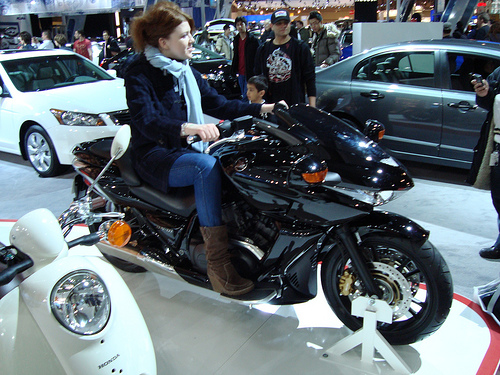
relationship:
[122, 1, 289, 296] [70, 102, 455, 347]
woman on bike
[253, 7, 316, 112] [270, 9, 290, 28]
man wearing hat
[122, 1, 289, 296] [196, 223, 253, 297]
woman wearing boot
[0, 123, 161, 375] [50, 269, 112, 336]
scooter has headlight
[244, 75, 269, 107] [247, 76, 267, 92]
boy has hair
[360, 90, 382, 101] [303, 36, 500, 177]
handle on car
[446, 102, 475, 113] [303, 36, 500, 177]
handle on car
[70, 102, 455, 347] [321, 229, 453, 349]
bike has wheel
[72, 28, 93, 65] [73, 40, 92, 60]
man wearing shirt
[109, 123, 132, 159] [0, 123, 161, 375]
mirror on scooter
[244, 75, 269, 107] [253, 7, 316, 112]
boy in front of man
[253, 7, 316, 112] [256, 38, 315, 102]
man wearing shirt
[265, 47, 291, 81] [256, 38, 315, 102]
design on shirt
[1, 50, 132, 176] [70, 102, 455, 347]
car behind bike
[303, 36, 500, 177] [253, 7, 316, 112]
car behind man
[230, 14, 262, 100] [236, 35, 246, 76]
man wearing shirt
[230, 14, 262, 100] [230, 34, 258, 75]
man wearing jacket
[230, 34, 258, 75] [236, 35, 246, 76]
jacket over shirt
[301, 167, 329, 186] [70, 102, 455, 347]
blinker on bike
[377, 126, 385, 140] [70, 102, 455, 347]
blinker on bike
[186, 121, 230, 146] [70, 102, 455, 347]
handle on bike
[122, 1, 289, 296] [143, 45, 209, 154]
woman wearing scarf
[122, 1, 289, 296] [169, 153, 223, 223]
woman wearing jeans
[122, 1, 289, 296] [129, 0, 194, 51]
woman has hair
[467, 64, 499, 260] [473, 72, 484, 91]
person holding phone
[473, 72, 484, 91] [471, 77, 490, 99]
phone in hand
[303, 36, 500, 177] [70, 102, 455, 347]
car near bike